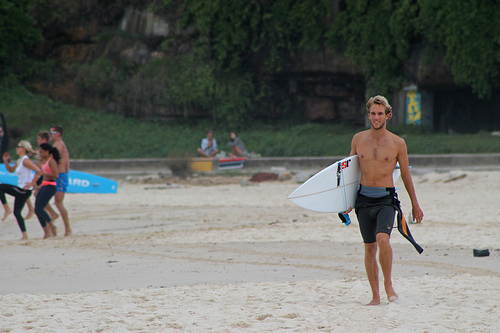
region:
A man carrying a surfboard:
[290, 90, 433, 307]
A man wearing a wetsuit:
[291, 87, 442, 303]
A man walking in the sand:
[295, 86, 430, 306]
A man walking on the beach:
[285, 92, 431, 312]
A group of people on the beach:
[2, 124, 84, 253]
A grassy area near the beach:
[7, 98, 452, 151]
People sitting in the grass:
[184, 119, 282, 158]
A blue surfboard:
[7, 148, 129, 195]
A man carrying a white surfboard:
[282, 144, 404, 216]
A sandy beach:
[52, 278, 342, 332]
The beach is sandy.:
[3, 91, 498, 331]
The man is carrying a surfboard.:
[275, 86, 437, 313]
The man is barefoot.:
[284, 92, 431, 312]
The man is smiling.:
[348, 91, 407, 139]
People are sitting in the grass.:
[153, 113, 268, 165]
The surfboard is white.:
[286, 96, 413, 225]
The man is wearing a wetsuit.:
[282, 99, 439, 310]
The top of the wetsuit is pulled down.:
[343, 94, 433, 309]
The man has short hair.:
[355, 84, 399, 140]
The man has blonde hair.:
[362, 88, 396, 140]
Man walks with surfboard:
[282, 94, 424, 308]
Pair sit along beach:
[193, 127, 252, 159]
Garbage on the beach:
[471, 244, 490, 257]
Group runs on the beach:
[0, 123, 74, 240]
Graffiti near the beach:
[400, 87, 421, 125]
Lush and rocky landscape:
[2, 5, 498, 150]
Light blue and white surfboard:
[0, 154, 117, 199]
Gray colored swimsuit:
[352, 180, 423, 256]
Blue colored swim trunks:
[52, 171, 69, 192]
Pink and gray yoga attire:
[34, 159, 58, 226]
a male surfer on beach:
[287, 92, 422, 305]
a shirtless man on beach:
[348, 95, 425, 307]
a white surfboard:
[285, 152, 412, 217]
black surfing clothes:
[353, 182, 423, 252]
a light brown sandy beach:
[3, 174, 498, 331]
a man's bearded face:
[366, 96, 388, 131]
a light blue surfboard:
[0, 158, 117, 193]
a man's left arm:
[396, 138, 425, 224]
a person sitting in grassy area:
[195, 128, 217, 154]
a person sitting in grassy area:
[223, 131, 246, 158]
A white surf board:
[285, 153, 412, 213]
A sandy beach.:
[1, 169, 499, 331]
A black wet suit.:
[352, 180, 422, 261]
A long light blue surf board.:
[0, 159, 118, 196]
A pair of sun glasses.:
[14, 143, 26, 147]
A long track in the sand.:
[77, 236, 497, 278]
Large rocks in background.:
[0, 0, 499, 131]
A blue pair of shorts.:
[54, 170, 69, 192]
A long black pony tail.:
[49, 146, 61, 166]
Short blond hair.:
[364, 95, 392, 117]